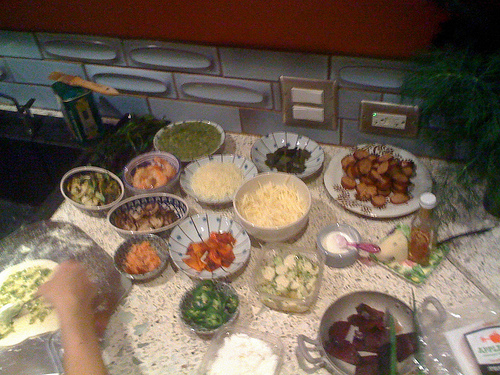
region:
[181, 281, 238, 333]
a dish filled with jalapeno slices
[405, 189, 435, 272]
a jar of some condiment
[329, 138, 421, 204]
a dish of sausage slices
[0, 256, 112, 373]
a hand is adding food to a plate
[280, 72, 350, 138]
a panel with power switches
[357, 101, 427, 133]
an electrical outlet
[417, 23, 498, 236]
a houseplant is placed on the table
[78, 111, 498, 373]
a table with several items of food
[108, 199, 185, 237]
a bowl of mushrooms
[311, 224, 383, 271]
a dish containing a purple spoon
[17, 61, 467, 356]
a table of different small dishes of food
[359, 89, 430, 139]
a silver and white outlet on the wall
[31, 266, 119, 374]
someone's hand and forearm reaching at a plate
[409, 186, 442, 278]
a bottle of sauce with a white cap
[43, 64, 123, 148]
a tin canister with a paint brush on top of it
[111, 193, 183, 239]
a bowl of sliced mushrooms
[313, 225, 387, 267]
a small glass bowl of white cream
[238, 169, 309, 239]
a large bowl of shredded cheese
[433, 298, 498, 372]
some plastic food packaging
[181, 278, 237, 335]
a small bowl of sliced jalapeno peppers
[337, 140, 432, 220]
plate of chips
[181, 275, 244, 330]
plate with raw jalapenos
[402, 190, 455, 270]
bottle of hot pepper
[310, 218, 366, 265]
small bowl of cream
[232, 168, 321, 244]
shredded white cheese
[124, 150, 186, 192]
bowl of large shrimp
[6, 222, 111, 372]
lady cooking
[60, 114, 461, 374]
table full of ingredients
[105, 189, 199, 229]
bowl of mushrooms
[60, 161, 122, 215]
bowl with vegetables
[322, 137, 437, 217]
Food on a plate with a brown design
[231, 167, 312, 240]
Food in a beige bowl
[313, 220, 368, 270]
Some type of sauce in a gray bowl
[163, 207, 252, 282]
A bowl containing some type of orange food.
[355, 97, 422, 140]
Electrical outlet on the wall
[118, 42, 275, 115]
Blue tiles on the wall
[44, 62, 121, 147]
paint brush resting on a tin can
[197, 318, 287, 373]
Some type of white substance in a clear container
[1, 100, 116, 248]
Sink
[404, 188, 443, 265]
Glass bottle with a white lid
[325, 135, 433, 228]
Bunch of cut sausage pieces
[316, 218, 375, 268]
Bowl of dressing with spoon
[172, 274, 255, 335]
Sliced green peppers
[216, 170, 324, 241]
Big white bowl of shredded cheese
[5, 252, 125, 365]
Hand spooning food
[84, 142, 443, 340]
Bowls of assorted food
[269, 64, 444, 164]
Electrical outlets with silver plates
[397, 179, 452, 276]
White capped bottle of sauce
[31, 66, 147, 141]
Wooden paint brush on top of green can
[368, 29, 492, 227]
Green bushy plant